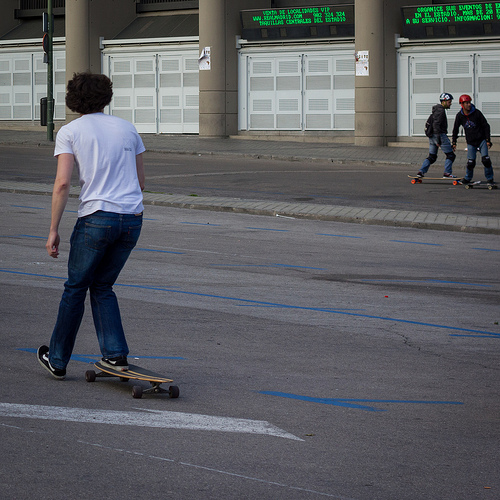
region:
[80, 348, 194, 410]
Man on a board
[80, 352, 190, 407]
Man is on a board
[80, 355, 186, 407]
Man on a skateboard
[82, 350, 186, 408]
Man is on a skateboard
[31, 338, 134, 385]
Man wearing shoes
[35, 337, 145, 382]
Man is wearing shoes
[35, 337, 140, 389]
Man wearing black and white shoes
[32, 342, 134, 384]
Man is wearing black and white shoes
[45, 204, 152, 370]
Man wearing blue jeans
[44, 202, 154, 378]
Man is wearing blue jeans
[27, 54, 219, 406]
he is skateboarding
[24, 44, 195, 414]
a guy skateboarding in the street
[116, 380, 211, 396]
the wheels are black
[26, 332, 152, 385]
these are black and white shoes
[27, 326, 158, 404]
the shoes are Vans brand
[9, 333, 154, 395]
the shoes are made by Vans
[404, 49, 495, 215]
they are wearing pads and helmets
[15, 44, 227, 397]
he is not wearing pads or helmets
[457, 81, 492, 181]
he is wearing a red helmet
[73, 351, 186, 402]
a black skateboard on the street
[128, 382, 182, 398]
the wheel of a skateboard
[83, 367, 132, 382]
the wheel of a skateboard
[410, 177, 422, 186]
the wheel of a skateboard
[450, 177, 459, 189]
the wheel of a skateboard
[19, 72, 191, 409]
a man riding a skateboard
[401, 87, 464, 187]
a man riding a skateboard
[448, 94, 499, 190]
a man riding a skateboard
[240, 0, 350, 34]
an electronic announcement board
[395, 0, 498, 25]
an electronic announcement board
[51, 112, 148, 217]
white shirt on the boy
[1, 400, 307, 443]
white arrow in the street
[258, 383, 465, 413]
blue lines in the street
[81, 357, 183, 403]
black and tan skateboard in the street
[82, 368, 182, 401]
black wheels on the skateboard in the street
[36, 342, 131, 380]
black and white shoes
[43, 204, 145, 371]
blue jeans on the skateboarder in the street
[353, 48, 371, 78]
white flyer on the building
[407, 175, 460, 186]
red wheels on the skateboard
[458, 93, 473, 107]
red helmet on the skateboarder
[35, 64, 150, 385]
skateboarder in white tee shirt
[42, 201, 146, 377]
men's blue denim jeans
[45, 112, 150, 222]
men's white tee shirt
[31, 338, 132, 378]
black and white athletic shoes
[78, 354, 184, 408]
black and yellow skateboard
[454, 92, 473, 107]
red safety sports helmet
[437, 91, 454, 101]
black and white sports helmet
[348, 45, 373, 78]
white flyer on concrete pillar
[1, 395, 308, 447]
left turn arrow on street